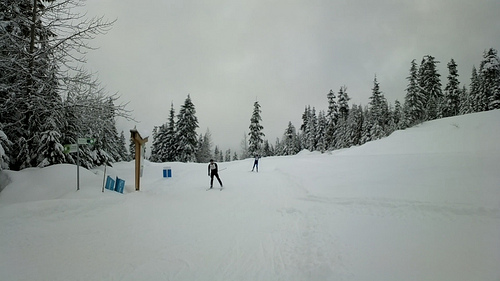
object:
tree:
[169, 92, 201, 161]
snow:
[270, 153, 400, 225]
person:
[205, 158, 224, 191]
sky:
[175, 13, 331, 73]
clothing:
[208, 161, 224, 190]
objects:
[105, 174, 123, 193]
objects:
[162, 169, 171, 178]